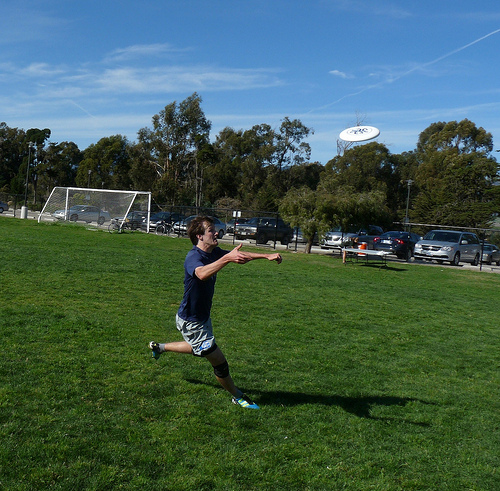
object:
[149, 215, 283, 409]
man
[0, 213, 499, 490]
field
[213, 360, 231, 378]
brace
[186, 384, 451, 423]
shadow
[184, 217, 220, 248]
head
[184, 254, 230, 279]
arm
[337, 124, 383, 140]
frisbee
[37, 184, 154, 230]
goal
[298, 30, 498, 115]
vapor trail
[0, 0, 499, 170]
sky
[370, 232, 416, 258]
car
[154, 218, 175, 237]
bike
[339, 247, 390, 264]
table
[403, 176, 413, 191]
light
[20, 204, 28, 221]
trash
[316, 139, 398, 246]
tree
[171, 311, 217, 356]
shorts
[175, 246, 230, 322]
shirt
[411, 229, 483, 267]
van